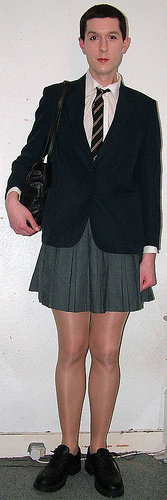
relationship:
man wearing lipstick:
[4, 3, 162, 498] [97, 57, 110, 64]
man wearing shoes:
[4, 3, 162, 498] [32, 444, 125, 499]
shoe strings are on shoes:
[45, 449, 119, 473] [32, 444, 125, 499]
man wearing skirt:
[4, 3, 162, 498] [28, 219, 155, 314]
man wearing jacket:
[4, 3, 162, 498] [4, 73, 162, 255]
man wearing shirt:
[4, 3, 162, 498] [6, 69, 159, 256]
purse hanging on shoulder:
[20, 80, 69, 229] [34, 80, 72, 125]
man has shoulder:
[4, 3, 162, 498] [34, 80, 72, 125]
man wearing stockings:
[4, 3, 162, 498] [52, 309, 129, 455]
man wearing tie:
[4, 3, 162, 498] [89, 86, 112, 163]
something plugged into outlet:
[32, 447, 164, 465] [29, 441, 46, 459]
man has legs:
[4, 3, 162, 498] [48, 309, 136, 455]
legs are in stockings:
[48, 309, 136, 455] [52, 309, 129, 455]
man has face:
[4, 3, 162, 498] [78, 4, 131, 72]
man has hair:
[4, 3, 162, 498] [79, 4, 127, 43]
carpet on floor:
[0, 451, 166, 500] [2, 452, 166, 499]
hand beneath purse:
[4, 191, 40, 237] [20, 80, 69, 229]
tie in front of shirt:
[89, 86, 112, 163] [6, 69, 159, 256]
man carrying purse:
[4, 3, 162, 498] [20, 80, 69, 229]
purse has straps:
[20, 80, 69, 229] [39, 80, 70, 162]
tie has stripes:
[89, 86, 112, 163] [92, 93, 104, 161]